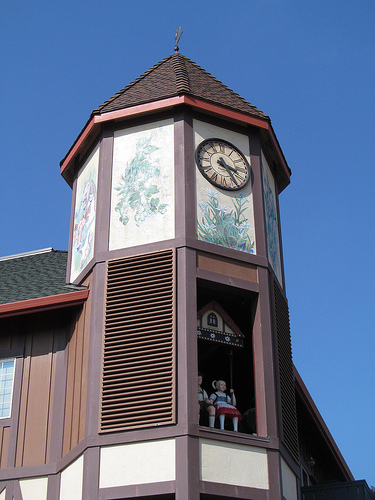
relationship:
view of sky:
[1, 4, 373, 493] [6, 4, 371, 489]